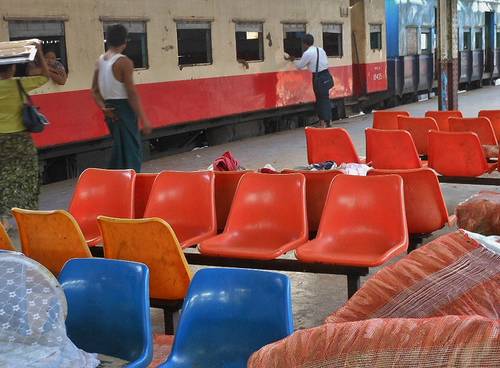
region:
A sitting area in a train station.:
[6, 85, 486, 358]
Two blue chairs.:
[53, 246, 313, 366]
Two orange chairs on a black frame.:
[8, 190, 186, 310]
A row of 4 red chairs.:
[65, 151, 407, 266]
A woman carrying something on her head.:
[3, 28, 53, 215]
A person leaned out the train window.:
[11, 22, 71, 87]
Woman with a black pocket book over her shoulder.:
[0, 31, 50, 211]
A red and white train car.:
[16, 5, 386, 137]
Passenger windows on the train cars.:
[13, 3, 497, 83]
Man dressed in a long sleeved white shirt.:
[287, 23, 348, 128]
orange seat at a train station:
[60, 162, 139, 245]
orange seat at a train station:
[137, 170, 222, 255]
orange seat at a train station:
[197, 167, 318, 269]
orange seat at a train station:
[287, 167, 417, 279]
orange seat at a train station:
[300, 123, 366, 171]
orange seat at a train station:
[349, 120, 431, 181]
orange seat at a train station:
[422, 124, 497, 186]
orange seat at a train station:
[394, 112, 441, 149]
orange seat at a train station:
[365, 103, 411, 136]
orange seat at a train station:
[91, 210, 206, 304]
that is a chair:
[73, 167, 135, 222]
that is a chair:
[225, 179, 303, 249]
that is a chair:
[335, 171, 407, 248]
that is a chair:
[200, 267, 283, 343]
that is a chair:
[70, 257, 145, 337]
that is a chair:
[364, 129, 411, 169]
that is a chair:
[430, 127, 477, 170]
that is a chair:
[399, 114, 434, 134]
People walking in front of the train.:
[9, 1, 356, 145]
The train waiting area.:
[70, 159, 449, 361]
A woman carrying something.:
[0, 36, 66, 224]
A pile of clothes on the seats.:
[207, 152, 372, 184]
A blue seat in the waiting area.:
[160, 266, 303, 366]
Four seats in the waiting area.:
[60, 170, 435, 257]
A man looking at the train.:
[89, 17, 150, 173]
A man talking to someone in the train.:
[285, 31, 343, 130]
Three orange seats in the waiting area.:
[303, 123, 494, 178]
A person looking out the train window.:
[15, 31, 75, 86]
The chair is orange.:
[48, 154, 140, 258]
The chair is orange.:
[134, 158, 216, 270]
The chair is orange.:
[192, 165, 314, 268]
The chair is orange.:
[294, 170, 409, 290]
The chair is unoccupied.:
[45, 161, 142, 251]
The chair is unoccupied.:
[116, 153, 219, 271]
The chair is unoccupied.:
[191, 148, 316, 270]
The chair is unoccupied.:
[288, 164, 413, 274]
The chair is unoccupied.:
[156, 259, 301, 366]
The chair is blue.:
[153, 260, 304, 367]